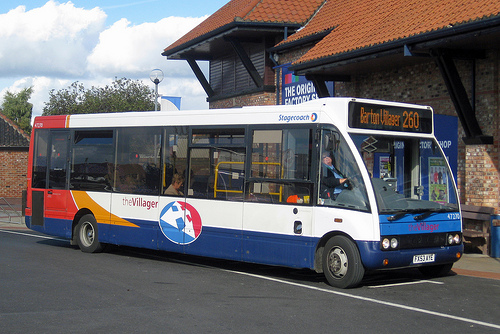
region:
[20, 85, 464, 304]
a red white and blue bus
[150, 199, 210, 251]
white arrows on the bus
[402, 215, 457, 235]
red letters on front of bus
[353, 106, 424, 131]
orange words on front of bus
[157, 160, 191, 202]
a woman passenger seen through window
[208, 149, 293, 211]
a yellow handrail on bus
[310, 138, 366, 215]
driver of bus seen through window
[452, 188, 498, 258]
a brown bench along wall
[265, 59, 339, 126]
a blue sign on the building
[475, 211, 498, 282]
a blue trash can next to bench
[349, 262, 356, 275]
part of a wheel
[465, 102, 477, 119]
part of a building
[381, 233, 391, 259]
part of a light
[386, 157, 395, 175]
part of a windwo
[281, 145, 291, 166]
side of a window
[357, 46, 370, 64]
part of a roof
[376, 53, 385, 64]
part of a pipe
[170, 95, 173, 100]
part of a cloud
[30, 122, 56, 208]
Long window on bus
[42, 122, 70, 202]
Long window on bus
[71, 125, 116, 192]
Long window on bus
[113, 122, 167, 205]
Long window on bus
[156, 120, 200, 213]
Long window on bus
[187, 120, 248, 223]
Long window on bus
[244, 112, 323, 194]
Long window on bus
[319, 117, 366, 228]
Long window on bus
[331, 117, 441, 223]
Long window on bus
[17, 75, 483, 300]
Red white and blue bus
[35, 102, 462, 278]
A bus parked by the building.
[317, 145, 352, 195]
The driver on the bus.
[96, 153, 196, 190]
Passengers on the bus.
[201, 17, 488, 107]
A building next to the bus.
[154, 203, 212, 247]
A red white and blue circle on side of bus.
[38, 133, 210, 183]
The bus has windows.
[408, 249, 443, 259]
white license plate on the bus.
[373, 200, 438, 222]
Wipers on the bus.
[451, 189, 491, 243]
A bench in front of the store.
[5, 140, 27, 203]
A brick building behind the bus.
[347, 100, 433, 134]
marquee has orange writing on it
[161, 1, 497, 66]
roof on building is red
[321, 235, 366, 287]
wheels on bus are gray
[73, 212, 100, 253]
wheels on bus are gray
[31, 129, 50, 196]
window is next to window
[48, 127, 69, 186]
window is next to window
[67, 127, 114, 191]
window is next to window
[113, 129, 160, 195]
window is next to window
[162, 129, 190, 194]
window is next to window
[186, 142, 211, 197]
window is next to window